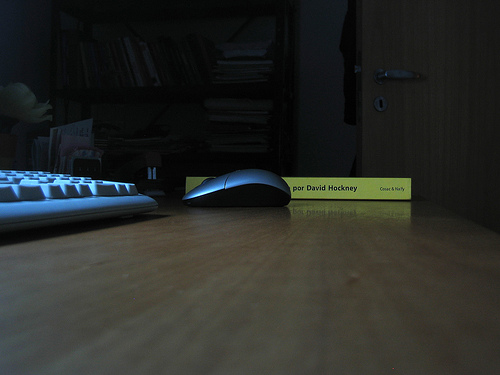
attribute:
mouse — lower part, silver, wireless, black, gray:
[194, 175, 303, 211]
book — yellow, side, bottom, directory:
[151, 176, 421, 200]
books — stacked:
[72, 31, 273, 159]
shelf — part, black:
[46, 8, 276, 176]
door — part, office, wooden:
[357, 4, 498, 205]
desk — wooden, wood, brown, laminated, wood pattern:
[26, 159, 445, 374]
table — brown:
[55, 199, 497, 367]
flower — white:
[4, 93, 72, 127]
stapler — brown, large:
[98, 142, 162, 199]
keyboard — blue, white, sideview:
[8, 167, 146, 229]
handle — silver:
[372, 70, 425, 80]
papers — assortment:
[43, 135, 114, 174]